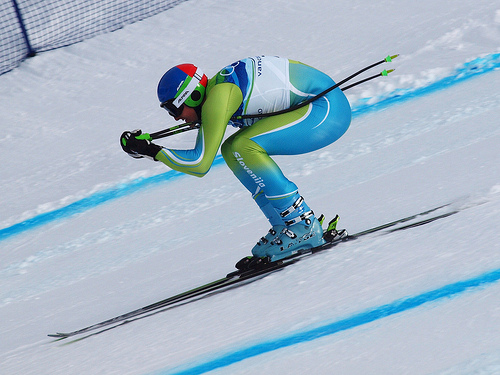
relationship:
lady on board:
[117, 50, 364, 240] [49, 194, 484, 342]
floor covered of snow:
[30, 114, 100, 195] [0, 184, 215, 316]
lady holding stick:
[119, 54, 351, 259] [332, 42, 399, 67]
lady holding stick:
[119, 54, 351, 259] [337, 66, 397, 93]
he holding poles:
[118, 54, 407, 268] [134, 51, 407, 142]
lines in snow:
[12, 54, 499, 373] [3, 1, 498, 366]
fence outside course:
[2, 2, 190, 75] [0, 0, 499, 373]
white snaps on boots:
[281, 195, 311, 225] [253, 192, 324, 259]